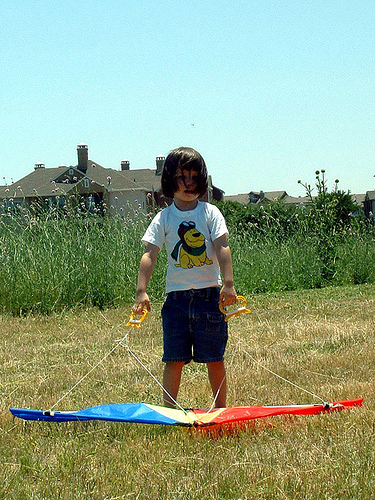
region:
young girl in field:
[130, 140, 251, 410]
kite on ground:
[21, 380, 343, 452]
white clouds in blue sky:
[21, 36, 72, 83]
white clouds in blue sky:
[200, 23, 230, 57]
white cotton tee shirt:
[142, 200, 225, 289]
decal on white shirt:
[170, 221, 213, 269]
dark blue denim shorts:
[159, 287, 228, 360]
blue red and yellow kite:
[7, 397, 365, 428]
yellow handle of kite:
[218, 294, 248, 322]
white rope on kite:
[47, 328, 188, 413]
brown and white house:
[2, 143, 221, 218]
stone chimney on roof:
[76, 146, 89, 163]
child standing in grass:
[131, 147, 249, 409]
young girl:
[141, 144, 239, 393]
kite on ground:
[26, 398, 369, 438]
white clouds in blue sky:
[303, 122, 357, 159]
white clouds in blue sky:
[280, 6, 323, 54]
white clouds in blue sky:
[281, 24, 352, 76]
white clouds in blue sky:
[21, 41, 66, 69]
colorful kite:
[33, 393, 345, 439]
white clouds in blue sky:
[316, 59, 351, 99]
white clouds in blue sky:
[55, 19, 98, 52]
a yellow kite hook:
[124, 307, 149, 328]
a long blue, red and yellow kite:
[9, 376, 362, 425]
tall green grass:
[233, 205, 373, 288]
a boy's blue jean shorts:
[156, 286, 231, 361]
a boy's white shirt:
[137, 198, 229, 293]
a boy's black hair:
[160, 144, 207, 202]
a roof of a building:
[2, 166, 65, 193]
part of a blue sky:
[169, 0, 326, 75]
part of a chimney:
[76, 141, 87, 165]